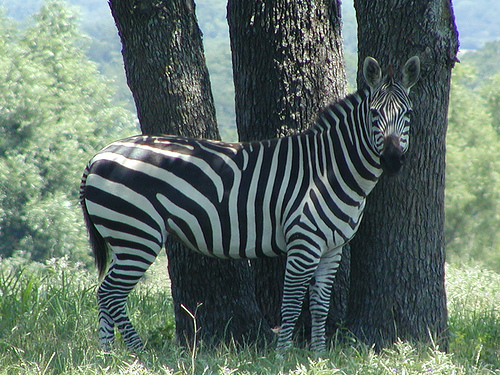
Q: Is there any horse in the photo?
A: No, there are no horses.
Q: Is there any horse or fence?
A: No, there are no horses or fences.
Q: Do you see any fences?
A: No, there are no fences.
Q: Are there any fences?
A: No, there are no fences.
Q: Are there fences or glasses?
A: No, there are no fences or glasses.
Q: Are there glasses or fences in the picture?
A: No, there are no fences or glasses.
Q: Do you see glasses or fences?
A: No, there are no fences or glasses.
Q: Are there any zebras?
A: Yes, there is a zebra.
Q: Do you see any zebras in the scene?
A: Yes, there is a zebra.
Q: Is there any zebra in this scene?
A: Yes, there is a zebra.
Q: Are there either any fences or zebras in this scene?
A: Yes, there is a zebra.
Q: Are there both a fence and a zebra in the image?
A: No, there is a zebra but no fences.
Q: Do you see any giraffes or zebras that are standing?
A: Yes, the zebra is standing.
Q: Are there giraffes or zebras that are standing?
A: Yes, the zebra is standing.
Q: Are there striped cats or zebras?
A: Yes, there is a striped zebra.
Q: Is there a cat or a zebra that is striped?
A: Yes, the zebra is striped.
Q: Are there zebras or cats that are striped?
A: Yes, the zebra is striped.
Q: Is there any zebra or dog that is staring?
A: Yes, the zebra is staring.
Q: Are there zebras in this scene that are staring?
A: Yes, there is a zebra that is staring.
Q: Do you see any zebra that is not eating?
A: Yes, there is a zebra that is staring .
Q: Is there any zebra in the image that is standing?
A: Yes, there is a zebra that is standing.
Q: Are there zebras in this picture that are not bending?
A: Yes, there is a zebra that is standing.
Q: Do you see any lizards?
A: No, there are no lizards.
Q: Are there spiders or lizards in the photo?
A: No, there are no lizards or spiders.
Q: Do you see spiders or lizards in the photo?
A: No, there are no lizards or spiders.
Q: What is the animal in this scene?
A: The animal is a zebra.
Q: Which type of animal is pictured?
A: The animal is a zebra.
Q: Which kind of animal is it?
A: The animal is a zebra.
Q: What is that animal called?
A: This is a zebra.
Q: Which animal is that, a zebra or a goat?
A: This is a zebra.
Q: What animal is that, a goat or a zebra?
A: This is a zebra.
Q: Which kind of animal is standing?
A: The animal is a zebra.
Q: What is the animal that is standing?
A: The animal is a zebra.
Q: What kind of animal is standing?
A: The animal is a zebra.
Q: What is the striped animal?
A: The animal is a zebra.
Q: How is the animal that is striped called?
A: The animal is a zebra.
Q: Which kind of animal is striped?
A: The animal is a zebra.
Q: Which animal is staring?
A: The animal is a zebra.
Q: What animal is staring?
A: The animal is a zebra.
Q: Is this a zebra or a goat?
A: This is a zebra.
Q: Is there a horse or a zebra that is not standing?
A: No, there is a zebra but it is standing.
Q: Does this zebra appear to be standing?
A: Yes, the zebra is standing.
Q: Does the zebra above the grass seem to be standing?
A: Yes, the zebra is standing.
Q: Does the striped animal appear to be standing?
A: Yes, the zebra is standing.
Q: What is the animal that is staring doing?
A: The zebra is standing.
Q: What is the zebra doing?
A: The zebra is standing.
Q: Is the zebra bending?
A: No, the zebra is standing.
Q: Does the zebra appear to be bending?
A: No, the zebra is standing.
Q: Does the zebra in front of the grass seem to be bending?
A: No, the zebra is standing.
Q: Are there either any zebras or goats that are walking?
A: No, there is a zebra but it is standing.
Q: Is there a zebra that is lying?
A: No, there is a zebra but it is standing.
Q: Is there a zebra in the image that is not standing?
A: No, there is a zebra but it is standing.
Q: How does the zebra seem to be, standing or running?
A: The zebra is standing.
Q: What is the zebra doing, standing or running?
A: The zebra is standing.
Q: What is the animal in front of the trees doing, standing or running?
A: The zebra is standing.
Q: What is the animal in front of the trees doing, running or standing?
A: The zebra is standing.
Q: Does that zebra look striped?
A: Yes, the zebra is striped.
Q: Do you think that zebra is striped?
A: Yes, the zebra is striped.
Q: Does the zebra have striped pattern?
A: Yes, the zebra is striped.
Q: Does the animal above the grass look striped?
A: Yes, the zebra is striped.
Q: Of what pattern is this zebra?
A: The zebra is striped.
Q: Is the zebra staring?
A: Yes, the zebra is staring.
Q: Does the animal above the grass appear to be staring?
A: Yes, the zebra is staring.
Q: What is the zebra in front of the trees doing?
A: The zebra is staring.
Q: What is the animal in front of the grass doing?
A: The zebra is staring.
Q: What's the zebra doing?
A: The zebra is staring.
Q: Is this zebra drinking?
A: No, the zebra is staring.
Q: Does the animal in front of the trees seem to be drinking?
A: No, the zebra is staring.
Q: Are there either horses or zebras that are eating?
A: No, there is a zebra but it is staring.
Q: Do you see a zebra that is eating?
A: No, there is a zebra but it is staring.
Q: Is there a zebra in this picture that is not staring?
A: No, there is a zebra but it is staring.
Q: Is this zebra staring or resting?
A: The zebra is staring.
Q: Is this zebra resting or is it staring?
A: The zebra is staring.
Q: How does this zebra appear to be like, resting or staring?
A: The zebra is staring.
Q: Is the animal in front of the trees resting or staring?
A: The zebra is staring.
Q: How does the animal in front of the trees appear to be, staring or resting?
A: The zebra is staring.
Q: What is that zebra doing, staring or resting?
A: The zebra is staring.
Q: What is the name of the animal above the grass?
A: The animal is a zebra.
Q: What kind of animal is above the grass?
A: The animal is a zebra.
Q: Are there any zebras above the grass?
A: Yes, there is a zebra above the grass.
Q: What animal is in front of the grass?
A: The zebra is in front of the grass.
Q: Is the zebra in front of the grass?
A: Yes, the zebra is in front of the grass.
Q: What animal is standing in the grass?
A: The zebra is standing in the grass.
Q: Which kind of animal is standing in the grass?
A: The animal is a zebra.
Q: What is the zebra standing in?
A: The zebra is standing in the grass.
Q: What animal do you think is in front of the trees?
A: The zebra is in front of the trees.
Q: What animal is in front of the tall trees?
A: The zebra is in front of the trees.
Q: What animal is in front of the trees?
A: The zebra is in front of the trees.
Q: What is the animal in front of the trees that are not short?
A: The animal is a zebra.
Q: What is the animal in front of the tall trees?
A: The animal is a zebra.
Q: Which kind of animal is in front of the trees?
A: The animal is a zebra.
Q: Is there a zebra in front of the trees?
A: Yes, there is a zebra in front of the trees.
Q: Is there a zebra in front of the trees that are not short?
A: Yes, there is a zebra in front of the trees.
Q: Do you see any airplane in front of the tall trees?
A: No, there is a zebra in front of the trees.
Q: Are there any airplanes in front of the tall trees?
A: No, there is a zebra in front of the trees.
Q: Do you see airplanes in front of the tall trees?
A: No, there is a zebra in front of the trees.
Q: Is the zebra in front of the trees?
A: Yes, the zebra is in front of the trees.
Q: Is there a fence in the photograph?
A: No, there are no fences.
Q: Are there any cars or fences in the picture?
A: No, there are no fences or cars.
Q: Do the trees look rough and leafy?
A: Yes, the trees are rough and leafy.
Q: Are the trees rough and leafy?
A: Yes, the trees are rough and leafy.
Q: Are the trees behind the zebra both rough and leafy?
A: Yes, the trees are rough and leafy.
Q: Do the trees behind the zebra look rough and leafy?
A: Yes, the trees are rough and leafy.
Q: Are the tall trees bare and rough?
A: No, the trees are rough but leafy.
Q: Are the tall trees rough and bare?
A: No, the trees are rough but leafy.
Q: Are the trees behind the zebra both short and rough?
A: No, the trees are rough but tall.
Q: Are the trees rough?
A: Yes, the trees are rough.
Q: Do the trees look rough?
A: Yes, the trees are rough.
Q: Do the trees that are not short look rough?
A: Yes, the trees are rough.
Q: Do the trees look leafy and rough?
A: Yes, the trees are leafy and rough.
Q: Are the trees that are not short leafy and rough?
A: Yes, the trees are leafy and rough.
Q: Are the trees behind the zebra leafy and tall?
A: Yes, the trees are leafy and tall.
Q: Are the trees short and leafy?
A: No, the trees are leafy but tall.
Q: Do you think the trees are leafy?
A: Yes, the trees are leafy.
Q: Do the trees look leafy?
A: Yes, the trees are leafy.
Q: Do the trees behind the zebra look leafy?
A: Yes, the trees are leafy.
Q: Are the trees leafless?
A: No, the trees are leafy.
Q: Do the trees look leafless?
A: No, the trees are leafy.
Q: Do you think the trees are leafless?
A: No, the trees are leafy.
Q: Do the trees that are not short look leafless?
A: No, the trees are leafy.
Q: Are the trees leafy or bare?
A: The trees are leafy.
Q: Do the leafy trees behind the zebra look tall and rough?
A: Yes, the trees are tall and rough.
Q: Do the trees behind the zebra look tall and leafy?
A: Yes, the trees are tall and leafy.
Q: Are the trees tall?
A: Yes, the trees are tall.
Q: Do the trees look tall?
A: Yes, the trees are tall.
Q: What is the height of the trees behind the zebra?
A: The trees are tall.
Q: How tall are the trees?
A: The trees are tall.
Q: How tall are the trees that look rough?
A: The trees are tall.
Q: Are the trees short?
A: No, the trees are tall.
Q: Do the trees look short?
A: No, the trees are tall.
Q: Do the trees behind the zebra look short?
A: No, the trees are tall.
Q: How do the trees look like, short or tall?
A: The trees are tall.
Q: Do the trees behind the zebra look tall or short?
A: The trees are tall.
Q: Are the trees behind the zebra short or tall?
A: The trees are tall.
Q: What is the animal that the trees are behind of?
A: The animal is a zebra.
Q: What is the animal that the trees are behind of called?
A: The animal is a zebra.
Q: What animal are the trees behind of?
A: The trees are behind the zebra.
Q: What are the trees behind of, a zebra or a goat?
A: The trees are behind a zebra.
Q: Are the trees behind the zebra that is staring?
A: Yes, the trees are behind the zebra.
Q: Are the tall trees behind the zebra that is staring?
A: Yes, the trees are behind the zebra.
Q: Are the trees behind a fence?
A: No, the trees are behind the zebra.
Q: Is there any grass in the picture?
A: Yes, there is grass.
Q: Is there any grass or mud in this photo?
A: Yes, there is grass.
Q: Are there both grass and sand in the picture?
A: No, there is grass but no sand.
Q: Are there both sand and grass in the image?
A: No, there is grass but no sand.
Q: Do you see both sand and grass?
A: No, there is grass but no sand.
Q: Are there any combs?
A: No, there are no combs.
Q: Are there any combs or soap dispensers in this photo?
A: No, there are no combs or soap dispensers.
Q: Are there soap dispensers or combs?
A: No, there are no combs or soap dispensers.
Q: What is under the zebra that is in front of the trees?
A: The grass is under the zebra.